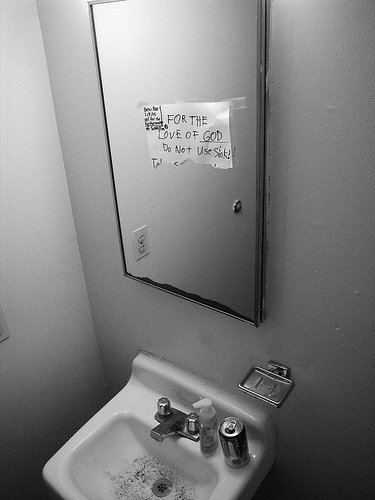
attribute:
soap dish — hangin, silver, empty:
[240, 363, 293, 408]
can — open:
[216, 416, 248, 467]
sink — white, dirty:
[34, 346, 280, 498]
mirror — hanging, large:
[82, 2, 270, 327]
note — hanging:
[138, 102, 233, 171]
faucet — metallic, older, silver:
[150, 397, 201, 443]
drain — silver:
[151, 476, 175, 498]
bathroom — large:
[6, 3, 374, 498]